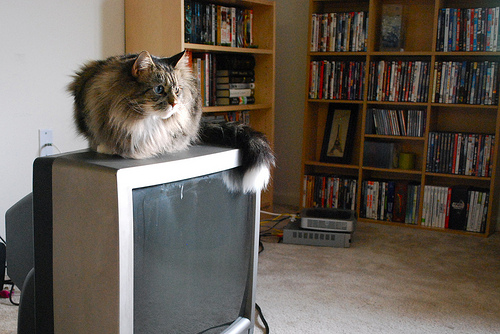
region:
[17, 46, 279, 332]
a cat in top of a television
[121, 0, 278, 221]
the book shelf behind the cat is brown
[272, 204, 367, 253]
electronics on the carpet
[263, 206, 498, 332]
the carpet is light brown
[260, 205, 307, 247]
wires are attached to the electronic equipment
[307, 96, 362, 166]
a picture on the shelf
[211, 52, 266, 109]
books are stacked on a shelf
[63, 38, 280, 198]
the cat is furry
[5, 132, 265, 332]
the television is silver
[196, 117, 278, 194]
the cat's tail is fluffy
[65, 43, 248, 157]
cat with blue eyes sitting on top of the TV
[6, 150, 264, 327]
large silver and black tv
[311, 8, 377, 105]
dvds sitting on shelves against the wall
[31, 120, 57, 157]
white cable cover with cable coming out of it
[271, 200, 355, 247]
silver electrical appliances sitting on the floor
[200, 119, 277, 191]
cat tail with a white tip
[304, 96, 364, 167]
picture sitting on a shelf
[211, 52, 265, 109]
books stacked on a shelf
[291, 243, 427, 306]
beige carpet on the floor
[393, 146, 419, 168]
green candle on the shelf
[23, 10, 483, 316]
cat in room with shelves and television set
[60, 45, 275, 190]
fluffy cat with long fur on TV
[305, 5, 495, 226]
divided shelves filled with book and artwork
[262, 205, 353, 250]
computer parts and cords on floor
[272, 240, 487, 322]
beige carpeting with foot marks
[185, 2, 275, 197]
bookcase with multicolored bookcovers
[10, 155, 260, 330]
thick television set with dirty gray screen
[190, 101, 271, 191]
tail curved over top and hanging down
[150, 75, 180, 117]
attentive eyes looking ahead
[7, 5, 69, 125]
blank light gray walls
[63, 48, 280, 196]
fluffy, golden, black and white sitting on top of a television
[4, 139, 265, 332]
silver-colored traditional television set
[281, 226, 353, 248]
dvd player sitting on the floor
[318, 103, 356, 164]
artwork depicting the Eiffel Tower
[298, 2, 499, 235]
media shelf holding various movies, video games and pieces of art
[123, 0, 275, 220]
media shelf holding various movies and books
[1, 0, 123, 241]
blank white colored wall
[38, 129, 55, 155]
cable outlet on a wall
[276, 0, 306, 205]
blank white wall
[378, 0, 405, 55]
piece of artwork sitting on a media shelf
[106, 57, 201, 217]
the cat is on top of the tv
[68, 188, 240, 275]
the tv is turned off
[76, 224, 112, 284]
the tv is silver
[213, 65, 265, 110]
the books are on the shelf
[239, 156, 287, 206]
the tip of the cats tail is white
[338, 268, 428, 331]
the carpet is cream in color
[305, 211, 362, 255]
the two receiver boxes are on the floor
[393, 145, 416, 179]
the cup is green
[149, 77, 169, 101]
the cat has a blue eye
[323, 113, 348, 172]
the picture is of the Eiffel tower